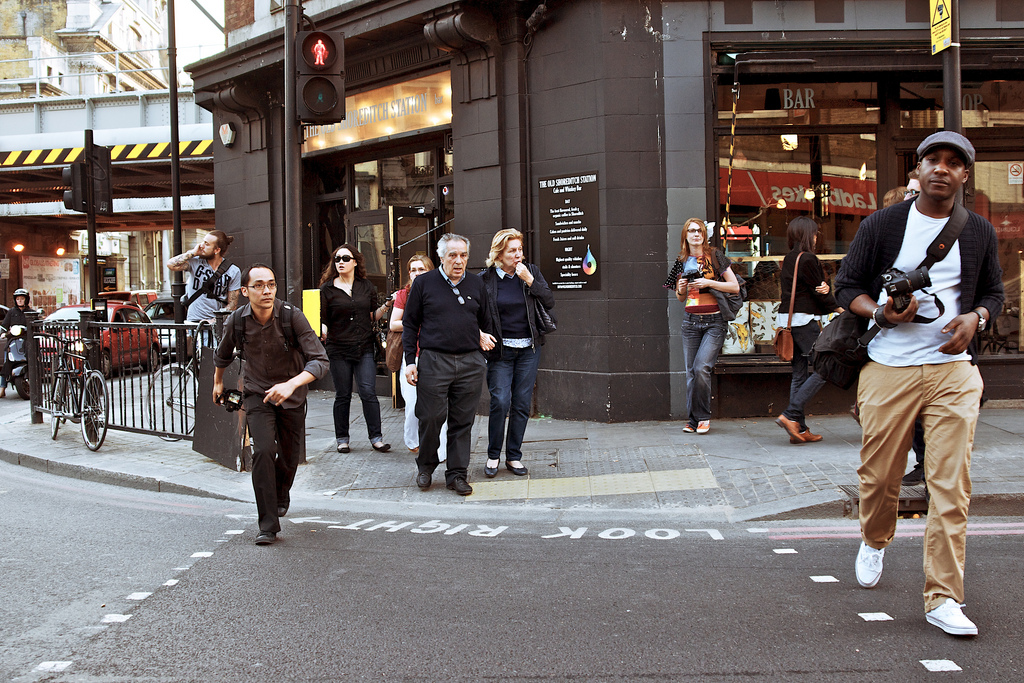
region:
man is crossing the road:
[822, 124, 1009, 641]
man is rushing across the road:
[201, 259, 338, 553]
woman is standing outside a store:
[664, 212, 754, 437]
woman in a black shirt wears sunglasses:
[310, 239, 397, 461]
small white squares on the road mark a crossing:
[765, 538, 962, 672]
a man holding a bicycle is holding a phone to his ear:
[144, 227, 249, 446]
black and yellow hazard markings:
[5, 138, 217, 170]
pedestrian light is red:
[294, 23, 348, 128]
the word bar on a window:
[768, 81, 825, 119]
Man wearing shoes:
[845, 523, 988, 648]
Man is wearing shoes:
[848, 517, 985, 642]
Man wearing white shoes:
[851, 519, 991, 647]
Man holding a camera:
[877, 244, 954, 340]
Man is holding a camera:
[874, 257, 944, 333]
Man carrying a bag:
[795, 185, 979, 385]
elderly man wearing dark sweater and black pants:
[401, 228, 499, 497]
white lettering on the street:
[284, 511, 733, 543]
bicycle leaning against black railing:
[34, 329, 114, 448]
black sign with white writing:
[531, 168, 607, 293]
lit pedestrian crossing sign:
[287, 28, 349, 127]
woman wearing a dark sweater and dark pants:
[474, 227, 560, 478]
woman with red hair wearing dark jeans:
[670, 212, 741, 434]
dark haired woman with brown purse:
[770, 215, 835, 446]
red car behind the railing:
[32, 300, 163, 381]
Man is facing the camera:
[822, 125, 1023, 639]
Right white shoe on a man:
[924, 590, 981, 642]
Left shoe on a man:
[842, 535, 890, 587]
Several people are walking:
[162, 225, 571, 551]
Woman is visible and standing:
[668, 216, 754, 439]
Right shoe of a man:
[447, 468, 474, 500]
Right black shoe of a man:
[447, 472, 477, 501]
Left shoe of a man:
[415, 462, 435, 494]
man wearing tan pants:
[802, 121, 1008, 637]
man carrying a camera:
[802, 126, 989, 643]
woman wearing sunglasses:
[321, 240, 395, 462]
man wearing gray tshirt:
[171, 225, 241, 318]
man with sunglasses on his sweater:
[397, 230, 489, 503]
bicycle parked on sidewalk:
[41, 323, 117, 454]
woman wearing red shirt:
[388, 246, 442, 463]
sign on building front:
[533, 174, 607, 295]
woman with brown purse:
[767, 217, 840, 449]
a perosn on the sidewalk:
[380, 239, 479, 502]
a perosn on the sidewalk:
[793, 220, 852, 476]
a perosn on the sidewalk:
[654, 188, 735, 395]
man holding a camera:
[821, 113, 1006, 655]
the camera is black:
[860, 240, 951, 337]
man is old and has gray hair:
[403, 216, 486, 340]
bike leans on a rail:
[17, 300, 161, 459]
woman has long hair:
[306, 234, 399, 471]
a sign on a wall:
[524, 150, 613, 304]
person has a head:
[243, 270, 275, 310]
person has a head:
[331, 245, 361, 274]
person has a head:
[437, 236, 469, 275]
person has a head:
[918, 135, 972, 200]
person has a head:
[399, 254, 429, 287]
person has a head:
[200, 230, 232, 269]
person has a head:
[406, 252, 429, 284]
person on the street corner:
[212, 258, 312, 537]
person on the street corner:
[402, 229, 480, 502]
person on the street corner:
[471, 226, 541, 467]